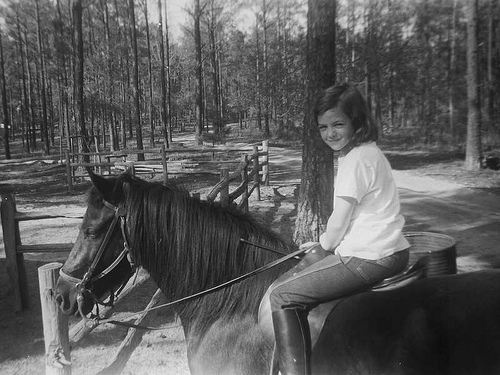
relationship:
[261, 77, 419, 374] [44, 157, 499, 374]
girl rides pony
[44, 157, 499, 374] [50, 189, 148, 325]
pony wears halter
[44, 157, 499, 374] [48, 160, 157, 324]
pony wears bridle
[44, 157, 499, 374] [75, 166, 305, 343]
pony has mane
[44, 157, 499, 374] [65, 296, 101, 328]
pony bites bit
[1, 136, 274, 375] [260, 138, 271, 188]
fence has post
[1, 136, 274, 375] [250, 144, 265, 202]
fence has post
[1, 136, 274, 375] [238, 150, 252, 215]
fence has post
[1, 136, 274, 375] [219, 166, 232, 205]
fence has post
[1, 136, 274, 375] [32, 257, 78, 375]
fence has post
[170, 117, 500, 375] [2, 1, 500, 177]
road winds through trees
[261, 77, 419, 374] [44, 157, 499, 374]
girl on pony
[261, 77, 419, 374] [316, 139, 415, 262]
girl wears shirt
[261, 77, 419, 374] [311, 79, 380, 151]
girl has hair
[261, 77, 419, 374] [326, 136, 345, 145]
girl has smile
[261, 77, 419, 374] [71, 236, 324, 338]
girl holds reins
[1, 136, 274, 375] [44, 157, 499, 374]
fence beside pony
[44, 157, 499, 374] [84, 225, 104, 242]
pony has eye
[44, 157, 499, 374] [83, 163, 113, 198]
pony has ear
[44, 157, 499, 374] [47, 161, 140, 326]
pony has head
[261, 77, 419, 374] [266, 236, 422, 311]
girl wears jeans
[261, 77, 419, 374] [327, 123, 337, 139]
girl has nose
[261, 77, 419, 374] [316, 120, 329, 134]
girl has eye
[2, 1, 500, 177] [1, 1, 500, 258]
trees are in background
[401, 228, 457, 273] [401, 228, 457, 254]
can has rim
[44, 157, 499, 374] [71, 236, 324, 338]
pony has reins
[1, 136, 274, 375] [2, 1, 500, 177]
fence before trees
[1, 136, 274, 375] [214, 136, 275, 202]
fence has corner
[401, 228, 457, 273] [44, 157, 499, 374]
can behind pony